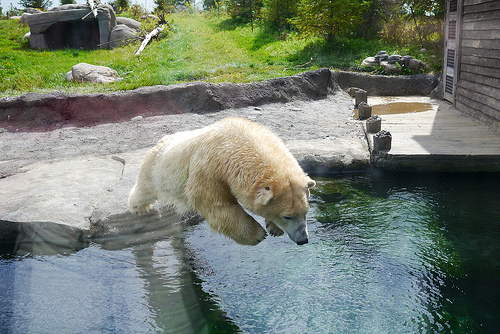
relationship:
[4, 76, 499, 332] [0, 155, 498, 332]
pool of pool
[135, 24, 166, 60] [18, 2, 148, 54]
tree branch near cave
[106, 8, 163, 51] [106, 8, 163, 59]
pile of pile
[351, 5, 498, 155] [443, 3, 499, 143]
patio outside building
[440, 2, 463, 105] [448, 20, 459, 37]
door with panels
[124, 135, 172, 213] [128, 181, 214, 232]
leg pushing off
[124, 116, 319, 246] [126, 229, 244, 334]
animal casts shadow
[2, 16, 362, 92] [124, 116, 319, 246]
grass behind animal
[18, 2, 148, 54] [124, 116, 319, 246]
cave for animal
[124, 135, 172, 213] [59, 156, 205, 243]
legs touching rock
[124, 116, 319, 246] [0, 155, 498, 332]
animal jump into pool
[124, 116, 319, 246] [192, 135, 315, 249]
animal has fur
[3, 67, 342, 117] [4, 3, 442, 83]
embankment between grass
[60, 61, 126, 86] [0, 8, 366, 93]
rock laying in grass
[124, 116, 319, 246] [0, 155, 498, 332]
animal diving in pool